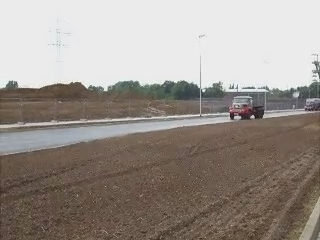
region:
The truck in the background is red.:
[228, 93, 254, 119]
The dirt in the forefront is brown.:
[115, 187, 172, 239]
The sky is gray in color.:
[104, 16, 148, 61]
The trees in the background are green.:
[168, 79, 199, 97]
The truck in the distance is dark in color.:
[306, 99, 319, 109]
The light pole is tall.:
[194, 34, 205, 117]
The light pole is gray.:
[196, 31, 203, 113]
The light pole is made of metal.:
[196, 34, 205, 120]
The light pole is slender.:
[197, 34, 203, 117]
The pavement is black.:
[15, 130, 61, 143]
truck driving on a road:
[229, 95, 265, 120]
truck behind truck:
[304, 97, 319, 111]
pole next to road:
[197, 33, 203, 116]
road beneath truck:
[0, 109, 319, 151]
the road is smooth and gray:
[1, 108, 319, 154]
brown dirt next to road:
[1, 112, 317, 239]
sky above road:
[0, 0, 319, 89]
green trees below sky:
[87, 79, 225, 98]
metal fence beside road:
[0, 95, 311, 124]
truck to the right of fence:
[228, 94, 265, 120]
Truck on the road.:
[227, 94, 265, 119]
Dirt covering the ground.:
[3, 113, 318, 239]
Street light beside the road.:
[195, 31, 210, 116]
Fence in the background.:
[1, 96, 318, 125]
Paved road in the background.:
[2, 107, 317, 156]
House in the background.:
[220, 85, 271, 102]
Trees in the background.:
[88, 78, 225, 102]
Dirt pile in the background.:
[36, 80, 87, 98]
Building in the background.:
[4, 77, 20, 91]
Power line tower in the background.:
[45, 15, 77, 88]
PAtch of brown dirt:
[17, 199, 79, 239]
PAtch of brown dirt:
[82, 199, 121, 231]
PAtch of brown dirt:
[119, 194, 149, 232]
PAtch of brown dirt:
[154, 194, 178, 239]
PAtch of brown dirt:
[183, 201, 199, 232]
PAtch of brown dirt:
[201, 209, 225, 233]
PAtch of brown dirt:
[234, 206, 263, 237]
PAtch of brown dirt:
[152, 163, 192, 193]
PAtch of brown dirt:
[216, 168, 264, 202]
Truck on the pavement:
[217, 85, 277, 134]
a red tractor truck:
[218, 78, 269, 130]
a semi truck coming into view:
[294, 92, 317, 119]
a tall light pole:
[188, 32, 206, 117]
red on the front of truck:
[229, 106, 250, 120]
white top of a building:
[216, 84, 275, 97]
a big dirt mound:
[24, 76, 87, 102]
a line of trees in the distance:
[92, 71, 208, 101]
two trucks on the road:
[219, 83, 317, 130]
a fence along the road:
[5, 92, 315, 124]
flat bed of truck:
[252, 102, 268, 118]